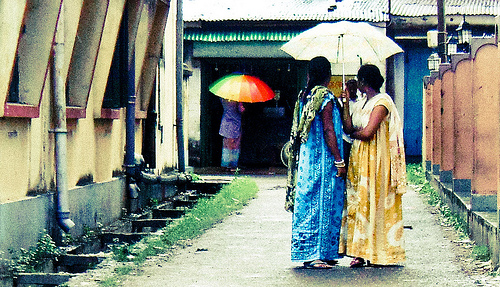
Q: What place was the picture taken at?
A: It was taken at the walkway.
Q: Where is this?
A: This is at the walkway.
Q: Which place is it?
A: It is a walkway.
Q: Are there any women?
A: Yes, there is a woman.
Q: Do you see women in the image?
A: Yes, there is a woman.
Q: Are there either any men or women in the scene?
A: Yes, there is a woman.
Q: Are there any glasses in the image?
A: No, there are no glasses.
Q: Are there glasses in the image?
A: No, there are no glasses.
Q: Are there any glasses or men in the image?
A: No, there are no glasses or men.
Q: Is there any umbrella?
A: Yes, there is an umbrella.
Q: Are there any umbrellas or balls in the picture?
A: Yes, there is an umbrella.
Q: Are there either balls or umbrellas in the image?
A: Yes, there is an umbrella.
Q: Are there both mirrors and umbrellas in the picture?
A: No, there is an umbrella but no mirrors.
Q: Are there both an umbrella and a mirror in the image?
A: No, there is an umbrella but no mirrors.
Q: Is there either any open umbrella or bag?
A: Yes, there is an open umbrella.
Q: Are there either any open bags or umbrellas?
A: Yes, there is an open umbrella.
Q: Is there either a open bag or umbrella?
A: Yes, there is an open umbrella.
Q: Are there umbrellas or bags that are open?
A: Yes, the umbrella is open.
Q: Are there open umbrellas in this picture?
A: Yes, there is an open umbrella.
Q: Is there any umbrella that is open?
A: Yes, there is an umbrella that is open.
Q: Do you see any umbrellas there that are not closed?
A: Yes, there is a open umbrella.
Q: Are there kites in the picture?
A: No, there are no kites.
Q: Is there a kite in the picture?
A: No, there are no kites.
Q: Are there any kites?
A: No, there are no kites.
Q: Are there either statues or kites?
A: No, there are no kites or statues.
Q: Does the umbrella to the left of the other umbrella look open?
A: Yes, the umbrella is open.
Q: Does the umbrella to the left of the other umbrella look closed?
A: No, the umbrella is open.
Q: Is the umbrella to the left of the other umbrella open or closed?
A: The umbrella is open.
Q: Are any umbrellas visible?
A: Yes, there is an umbrella.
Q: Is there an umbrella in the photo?
A: Yes, there is an umbrella.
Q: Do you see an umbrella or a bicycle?
A: Yes, there is an umbrella.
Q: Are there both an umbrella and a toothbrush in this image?
A: No, there is an umbrella but no toothbrushes.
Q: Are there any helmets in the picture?
A: No, there are no helmets.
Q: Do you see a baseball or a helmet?
A: No, there are no helmets or baseballs.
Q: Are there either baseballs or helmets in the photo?
A: No, there are no helmets or baseballs.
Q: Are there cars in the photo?
A: No, there are no cars.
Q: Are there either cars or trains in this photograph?
A: No, there are no cars or trains.